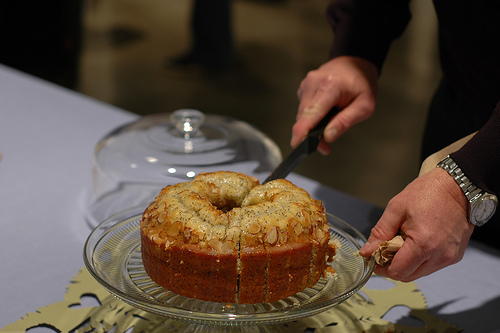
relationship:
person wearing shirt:
[326, 0, 497, 251] [282, 37, 478, 236]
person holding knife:
[288, 30, 446, 164] [229, 104, 380, 201]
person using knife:
[326, 0, 497, 251] [264, 105, 348, 182]